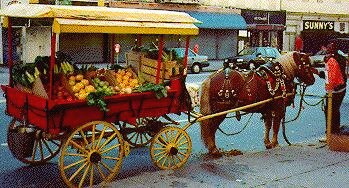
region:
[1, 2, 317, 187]
horse is in front of the carriage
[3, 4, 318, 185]
carriage is behind the horse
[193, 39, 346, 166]
human pets horse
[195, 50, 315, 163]
horse stands in own feces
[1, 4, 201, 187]
carriage holds fruit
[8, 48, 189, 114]
fruit is displayed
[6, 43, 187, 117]
fruit is for sale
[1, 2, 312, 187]
horse and carriage are parked next to sidewalk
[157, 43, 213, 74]
car is parked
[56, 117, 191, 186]
the wheel on the right is smaller than the wheel on the left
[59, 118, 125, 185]
a wooden cart wheel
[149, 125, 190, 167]
a wooden cart wheel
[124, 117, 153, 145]
a wooden cart wheel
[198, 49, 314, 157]
horse pulling a cart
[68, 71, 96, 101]
fruit on a cart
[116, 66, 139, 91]
fruit on a cart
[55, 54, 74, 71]
vegetables on a cart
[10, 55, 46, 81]
vegetables on a cart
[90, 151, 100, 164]
axle of a cart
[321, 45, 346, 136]
people standing on a sidewalk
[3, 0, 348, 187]
mobile fruit cart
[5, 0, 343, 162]
man standing beside horse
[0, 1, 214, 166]
fruit stand with red sides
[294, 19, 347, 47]
advertising sign reading "sunny's"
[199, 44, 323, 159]
brown horse with blonde mane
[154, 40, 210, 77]
grey car parked on curb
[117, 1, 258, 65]
geen awning on storefront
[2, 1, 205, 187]
fruit stand with yellow roof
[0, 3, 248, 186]
fruit stand with yellow wheels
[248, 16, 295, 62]
shelter on corner of busy street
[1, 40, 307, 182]
horse pulling wagon with fruits and vegetables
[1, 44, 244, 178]
red wagon with fruits and vegetables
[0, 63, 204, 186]
yellow wheels on wagon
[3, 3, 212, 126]
yellow roof on red wagon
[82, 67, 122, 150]
green apples in container on wagon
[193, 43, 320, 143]
brown horse with blonde mane and tail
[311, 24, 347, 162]
person wearing orange shirt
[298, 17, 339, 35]
black and white sign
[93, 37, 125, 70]
parking meter on sidewalk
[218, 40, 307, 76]
black car parked at curb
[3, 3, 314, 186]
Small kart carried by a horse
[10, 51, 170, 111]
Vegetables in the kart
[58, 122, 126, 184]
Right back wheel of the kart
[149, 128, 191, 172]
Front right wheel of the cart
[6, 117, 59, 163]
Left back wheel of the cart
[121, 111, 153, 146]
Front left wheel of the cart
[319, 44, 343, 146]
Person standing in front of the kart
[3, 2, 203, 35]
Yellow roof of the cart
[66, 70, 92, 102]
Oranges in the cart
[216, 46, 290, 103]
Buckle on top of the horse